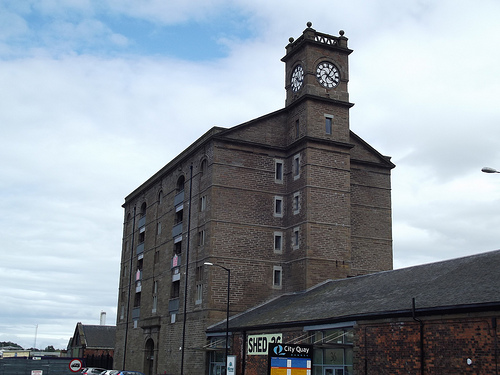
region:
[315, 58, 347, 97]
white clock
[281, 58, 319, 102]
white clock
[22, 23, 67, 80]
white clouds in blue sky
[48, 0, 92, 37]
white clouds in blue sky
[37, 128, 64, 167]
white clouds in blue sky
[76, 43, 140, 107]
white clouds in blue sky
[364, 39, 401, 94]
white clouds in blue sky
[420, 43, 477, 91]
white clouds in blue sky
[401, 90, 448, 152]
white clouds in blue sky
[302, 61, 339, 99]
white clock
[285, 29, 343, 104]
clocks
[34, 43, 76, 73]
white clouds in blue sky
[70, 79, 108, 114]
white clouds in blue sky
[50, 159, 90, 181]
white clouds in blue sky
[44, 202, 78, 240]
white clouds in blue sky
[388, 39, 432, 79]
white clouds in blue sky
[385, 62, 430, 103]
white clouds in blue sky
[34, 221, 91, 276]
white clouds in blue sky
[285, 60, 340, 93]
two clocks on the tower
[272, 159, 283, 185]
small opening on the building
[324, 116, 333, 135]
a window on the tower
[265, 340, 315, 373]
a business sign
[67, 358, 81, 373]
a red and white street sign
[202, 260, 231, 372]
a street light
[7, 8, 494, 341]
the skies are overscast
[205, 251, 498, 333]
a gray roof top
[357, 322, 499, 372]
a brick building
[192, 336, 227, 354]
an overhang above the door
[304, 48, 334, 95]
clock in clock tower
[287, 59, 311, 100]
clock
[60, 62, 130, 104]
white clouds in blue sky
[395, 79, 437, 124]
white clouds in blue sky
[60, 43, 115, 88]
white clouds in blue sky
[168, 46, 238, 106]
white clouds in blue sky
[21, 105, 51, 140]
white clouds in blue sky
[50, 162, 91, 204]
white clouds in blue sky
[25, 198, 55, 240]
white clouds in blue sky